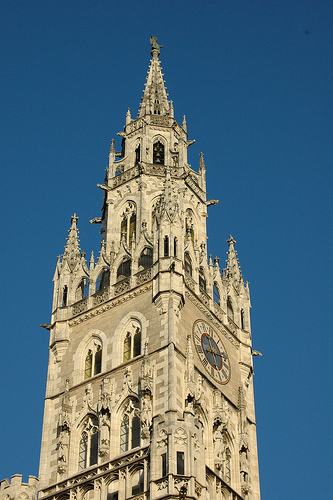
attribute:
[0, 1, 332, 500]
sky — clear, blue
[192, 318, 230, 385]
clock — round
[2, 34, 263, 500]
cathedral — roofed, gothic, light tan, mason-like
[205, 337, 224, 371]
arms — golden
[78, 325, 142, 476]
windows — arched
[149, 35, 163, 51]
statue — sculpted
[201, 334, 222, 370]
center — blue